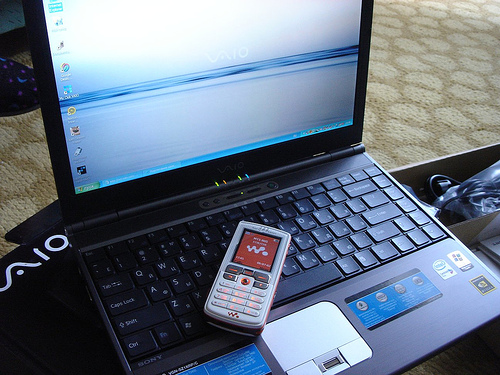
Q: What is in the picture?
A: A laptop and cellphone.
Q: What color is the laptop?
A: Black.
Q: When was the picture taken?
A: While the laptop was on.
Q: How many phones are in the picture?
A: One.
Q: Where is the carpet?
A: On the floor.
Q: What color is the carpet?
A: Brown.